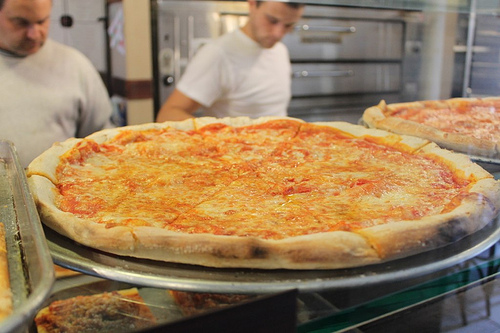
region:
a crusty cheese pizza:
[30, 90, 498, 281]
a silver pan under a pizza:
[25, 179, 499, 270]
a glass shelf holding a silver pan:
[10, 220, 497, 329]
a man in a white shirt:
[161, 2, 310, 124]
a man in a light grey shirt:
[5, 3, 119, 144]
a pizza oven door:
[242, 11, 450, 62]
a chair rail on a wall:
[98, 68, 160, 102]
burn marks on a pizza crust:
[208, 234, 271, 259]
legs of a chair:
[439, 265, 491, 325]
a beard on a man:
[246, 17, 277, 49]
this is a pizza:
[78, 130, 393, 237]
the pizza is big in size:
[75, 136, 420, 237]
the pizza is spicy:
[121, 145, 363, 217]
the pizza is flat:
[89, 137, 415, 228]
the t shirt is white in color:
[230, 50, 285, 111]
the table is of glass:
[347, 277, 429, 317]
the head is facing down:
[0, 2, 54, 59]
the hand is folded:
[161, 96, 189, 116]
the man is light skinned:
[253, 12, 268, 34]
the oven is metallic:
[306, 17, 396, 86]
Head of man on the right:
[0, 0, 47, 57]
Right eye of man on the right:
[5, 10, 25, 25]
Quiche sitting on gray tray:
[25, 115, 480, 290]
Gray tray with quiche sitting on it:
[25, 225, 490, 290]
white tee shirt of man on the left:
[171, 25, 291, 115]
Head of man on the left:
[248, 3, 305, 50]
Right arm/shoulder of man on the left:
[148, 18, 226, 120]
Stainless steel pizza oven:
[301, 11, 409, 101]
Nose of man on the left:
[266, 25, 291, 44]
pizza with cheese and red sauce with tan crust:
[26, 114, 498, 272]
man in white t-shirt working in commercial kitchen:
[158, 1, 308, 118]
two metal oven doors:
[156, 2, 425, 102]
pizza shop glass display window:
[3, 272, 499, 329]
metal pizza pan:
[46, 141, 498, 291]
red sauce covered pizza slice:
[34, 288, 153, 330]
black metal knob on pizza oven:
[158, 70, 176, 86]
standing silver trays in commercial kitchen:
[454, 4, 499, 94]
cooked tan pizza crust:
[138, 232, 317, 275]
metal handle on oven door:
[288, 66, 355, 83]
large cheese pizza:
[30, 109, 489, 264]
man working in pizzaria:
[2, 1, 103, 113]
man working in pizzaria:
[225, 4, 312, 115]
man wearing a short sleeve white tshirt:
[159, 3, 292, 115]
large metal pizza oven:
[303, 12, 422, 94]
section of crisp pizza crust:
[208, 239, 275, 264]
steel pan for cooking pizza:
[7, 139, 27, 244]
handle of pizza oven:
[297, 68, 359, 80]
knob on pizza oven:
[162, 72, 175, 86]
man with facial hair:
[244, 2, 306, 54]